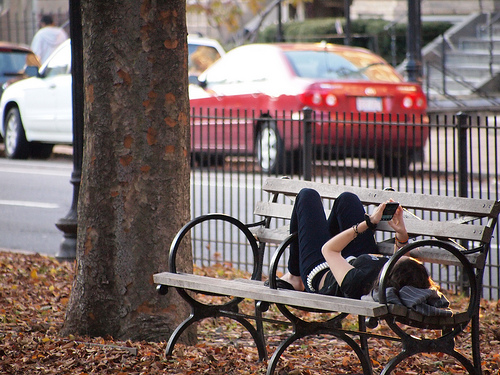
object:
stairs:
[386, 11, 495, 103]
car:
[193, 41, 427, 176]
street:
[7, 144, 498, 297]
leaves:
[2, 306, 373, 363]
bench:
[152, 170, 498, 375]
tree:
[61, 6, 192, 342]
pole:
[53, 3, 87, 261]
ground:
[1, 248, 488, 373]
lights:
[302, 89, 343, 109]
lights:
[396, 88, 430, 111]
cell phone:
[380, 200, 400, 222]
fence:
[191, 100, 498, 296]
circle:
[167, 212, 264, 308]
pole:
[254, 300, 267, 357]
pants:
[333, 191, 382, 259]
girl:
[264, 188, 432, 302]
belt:
[305, 254, 356, 294]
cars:
[0, 31, 227, 174]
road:
[0, 147, 484, 297]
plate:
[354, 93, 388, 112]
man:
[29, 12, 67, 66]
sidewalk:
[243, 123, 484, 173]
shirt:
[319, 253, 389, 296]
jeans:
[285, 185, 335, 294]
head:
[377, 256, 429, 290]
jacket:
[360, 285, 455, 318]